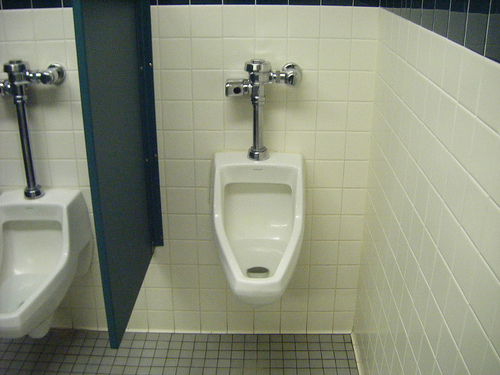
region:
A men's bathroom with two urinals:
[30, 34, 475, 374]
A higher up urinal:
[217, 69, 303, 303]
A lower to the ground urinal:
[1, 58, 60, 343]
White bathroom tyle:
[333, 35, 435, 323]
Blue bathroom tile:
[390, 4, 496, 42]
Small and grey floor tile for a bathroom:
[142, 343, 336, 368]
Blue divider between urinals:
[77, 17, 164, 321]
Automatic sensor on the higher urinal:
[227, 76, 246, 98]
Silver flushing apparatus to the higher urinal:
[226, 59, 298, 157]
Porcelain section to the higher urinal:
[214, 160, 305, 307]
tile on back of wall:
[348, 134, 373, 161]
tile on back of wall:
[339, 189, 361, 214]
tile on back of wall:
[308, 239, 338, 270]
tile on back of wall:
[313, 188, 335, 213]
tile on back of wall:
[320, 68, 347, 103]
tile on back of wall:
[194, 40, 220, 68]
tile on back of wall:
[162, 190, 190, 217]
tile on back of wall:
[166, 238, 200, 265]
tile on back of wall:
[172, 267, 198, 289]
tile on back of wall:
[173, 288, 197, 310]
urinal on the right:
[215, 61, 307, 300]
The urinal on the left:
[0, 58, 88, 339]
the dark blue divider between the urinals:
[73, 3, 165, 351]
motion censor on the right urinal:
[225, 80, 247, 93]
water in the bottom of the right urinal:
[235, 246, 280, 281]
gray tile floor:
[2, 330, 356, 373]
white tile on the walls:
[0, 8, 498, 368]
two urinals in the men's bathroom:
[0, 58, 300, 335]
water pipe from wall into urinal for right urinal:
[249, 60, 300, 157]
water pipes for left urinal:
[5, 60, 65, 200]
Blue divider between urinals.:
[73, 50, 158, 250]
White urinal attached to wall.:
[205, 155, 300, 300]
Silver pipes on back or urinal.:
[222, 64, 307, 135]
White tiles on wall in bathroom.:
[386, 93, 453, 285]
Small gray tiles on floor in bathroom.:
[227, 342, 331, 367]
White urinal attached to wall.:
[14, 204, 75, 310]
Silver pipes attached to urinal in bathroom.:
[11, 55, 63, 191]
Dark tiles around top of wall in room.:
[461, 32, 487, 63]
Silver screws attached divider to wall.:
[141, 53, 158, 184]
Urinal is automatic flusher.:
[231, 72, 253, 112]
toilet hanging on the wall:
[189, 56, 352, 318]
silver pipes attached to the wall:
[218, 58, 303, 156]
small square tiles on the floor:
[2, 327, 357, 371]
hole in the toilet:
[244, 257, 269, 281]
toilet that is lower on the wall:
[0, 58, 90, 358]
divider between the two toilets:
[67, 3, 199, 348]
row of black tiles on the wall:
[379, 2, 499, 71]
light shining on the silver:
[249, 63, 259, 72]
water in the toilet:
[3, 266, 38, 321]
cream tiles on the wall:
[147, 12, 367, 338]